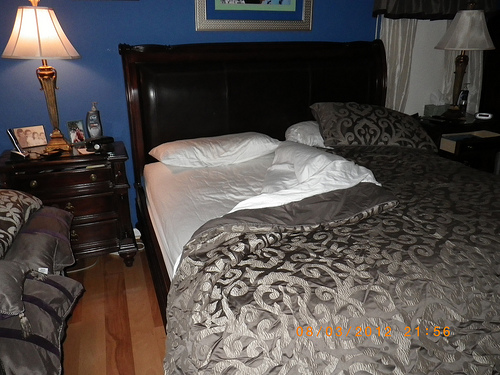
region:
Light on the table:
[4, 0, 76, 152]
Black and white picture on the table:
[4, 125, 54, 150]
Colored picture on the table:
[63, 115, 89, 149]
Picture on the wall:
[194, 2, 314, 34]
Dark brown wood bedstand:
[1, 136, 146, 273]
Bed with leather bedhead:
[116, 37, 491, 368]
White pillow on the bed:
[148, 130, 283, 170]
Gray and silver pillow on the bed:
[307, 94, 441, 153]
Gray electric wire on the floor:
[66, 241, 147, 273]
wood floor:
[62, 234, 171, 374]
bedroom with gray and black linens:
[0, 99, 498, 373]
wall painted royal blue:
[2, 1, 382, 226]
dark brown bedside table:
[0, 135, 140, 266]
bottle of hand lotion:
[83, 97, 103, 139]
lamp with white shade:
[1, 0, 82, 155]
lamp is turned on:
[1, 0, 81, 155]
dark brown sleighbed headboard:
[115, 38, 387, 223]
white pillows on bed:
[147, 121, 336, 168]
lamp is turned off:
[433, 8, 495, 120]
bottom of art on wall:
[192, 0, 314, 32]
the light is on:
[7, 11, 113, 128]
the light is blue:
[92, 17, 176, 32]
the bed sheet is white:
[155, 145, 262, 168]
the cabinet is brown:
[60, 159, 141, 258]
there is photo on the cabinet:
[8, 121, 48, 152]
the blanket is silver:
[279, 255, 467, 351]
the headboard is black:
[164, 43, 394, 105]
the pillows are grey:
[322, 105, 427, 151]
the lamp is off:
[445, 8, 489, 89]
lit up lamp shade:
[1, 3, 77, 61]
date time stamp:
[290, 322, 450, 334]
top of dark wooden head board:
[105, 40, 395, 135]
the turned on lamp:
[4, 2, 73, 137]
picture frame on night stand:
[7, 126, 48, 148]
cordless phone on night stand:
[3, 130, 28, 158]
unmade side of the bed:
[130, 132, 370, 263]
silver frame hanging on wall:
[193, 1, 315, 32]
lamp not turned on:
[435, 10, 493, 108]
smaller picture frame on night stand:
[65, 121, 87, 148]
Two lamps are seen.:
[6, 6, 498, 84]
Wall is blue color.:
[80, 15, 162, 39]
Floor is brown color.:
[91, 313, 171, 373]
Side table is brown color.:
[44, 148, 107, 250]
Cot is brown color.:
[123, 42, 354, 112]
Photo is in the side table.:
[8, 118, 71, 167]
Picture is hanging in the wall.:
[185, 3, 316, 37]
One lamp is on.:
[8, 7, 80, 104]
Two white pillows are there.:
[209, 126, 330, 157]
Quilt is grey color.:
[305, 258, 451, 306]